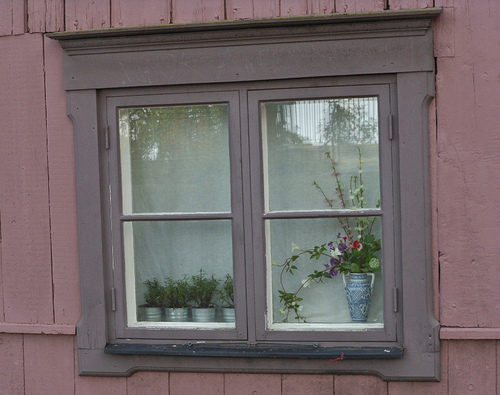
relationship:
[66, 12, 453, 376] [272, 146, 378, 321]
window with plant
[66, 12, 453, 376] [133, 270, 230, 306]
window with plant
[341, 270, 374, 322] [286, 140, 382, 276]
vase with flowers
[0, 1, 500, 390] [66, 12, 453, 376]
house with window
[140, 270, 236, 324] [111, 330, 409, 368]
plants in window sill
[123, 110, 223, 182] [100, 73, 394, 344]
tree reflected in window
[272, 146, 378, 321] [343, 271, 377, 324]
plant in vase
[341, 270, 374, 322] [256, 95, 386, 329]
vase in window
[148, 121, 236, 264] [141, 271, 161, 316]
curtain behind plant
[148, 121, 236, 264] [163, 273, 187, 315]
curtain behind plant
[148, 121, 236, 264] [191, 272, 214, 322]
curtain behind plant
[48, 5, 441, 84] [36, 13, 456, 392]
wood framed window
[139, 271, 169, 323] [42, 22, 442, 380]
plants inside window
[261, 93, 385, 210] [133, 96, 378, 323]
reflection in glass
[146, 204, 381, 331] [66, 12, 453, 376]
plants in window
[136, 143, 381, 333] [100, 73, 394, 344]
plants inside window